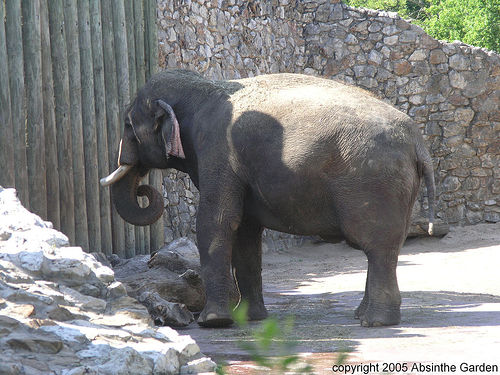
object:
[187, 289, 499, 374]
ground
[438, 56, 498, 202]
wall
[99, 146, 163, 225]
trunk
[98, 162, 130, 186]
tusk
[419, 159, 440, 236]
tail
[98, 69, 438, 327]
elephant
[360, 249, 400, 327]
legs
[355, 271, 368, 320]
legs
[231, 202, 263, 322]
leg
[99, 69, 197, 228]
head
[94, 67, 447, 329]
elephant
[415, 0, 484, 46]
trees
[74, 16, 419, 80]
enclosure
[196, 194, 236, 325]
leg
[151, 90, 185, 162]
ear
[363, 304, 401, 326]
foot